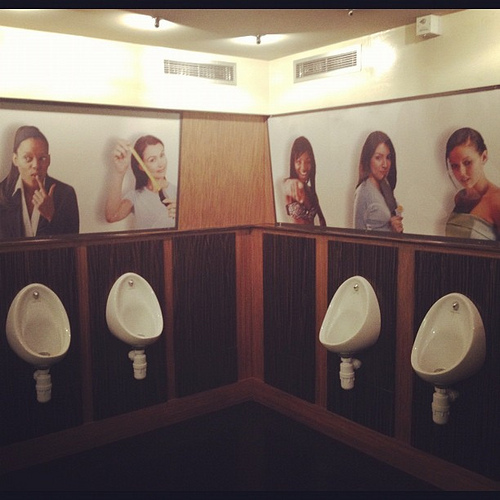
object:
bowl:
[316, 272, 382, 359]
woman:
[278, 133, 326, 226]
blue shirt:
[352, 179, 403, 235]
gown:
[444, 212, 498, 242]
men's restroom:
[1, 86, 498, 498]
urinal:
[4, 274, 73, 412]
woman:
[443, 125, 498, 240]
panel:
[256, 231, 315, 408]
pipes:
[336, 351, 361, 392]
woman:
[101, 135, 180, 236]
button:
[30, 287, 38, 299]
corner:
[211, 71, 318, 355]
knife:
[381, 175, 398, 214]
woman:
[347, 127, 404, 232]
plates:
[291, 43, 364, 86]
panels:
[408, 247, 497, 482]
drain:
[433, 366, 445, 373]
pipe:
[428, 378, 454, 425]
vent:
[168, 68, 232, 76]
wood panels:
[0, 227, 499, 482]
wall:
[252, 5, 499, 482]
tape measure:
[124, 142, 173, 209]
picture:
[266, 88, 498, 240]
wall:
[0, 9, 249, 464]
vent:
[287, 41, 364, 92]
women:
[3, 119, 82, 239]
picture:
[0, 108, 189, 242]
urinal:
[3, 278, 74, 404]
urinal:
[103, 270, 166, 380]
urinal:
[318, 271, 386, 392]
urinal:
[408, 290, 490, 425]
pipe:
[124, 346, 152, 380]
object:
[394, 206, 404, 220]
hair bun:
[443, 125, 488, 162]